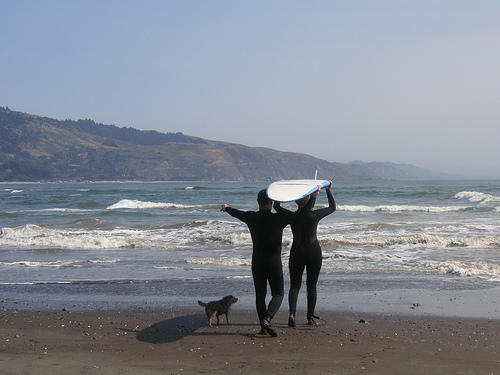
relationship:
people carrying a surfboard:
[219, 186, 323, 337] [264, 176, 332, 205]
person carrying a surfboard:
[274, 184, 337, 326] [240, 163, 392, 219]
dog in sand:
[193, 292, 241, 327] [161, 315, 365, 373]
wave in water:
[412, 252, 498, 287] [5, 175, 499, 287]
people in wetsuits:
[219, 186, 323, 337] [225, 197, 317, 320]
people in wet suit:
[219, 186, 323, 337] [225, 205, 287, 339]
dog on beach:
[193, 292, 241, 327] [1, 276, 498, 372]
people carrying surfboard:
[219, 186, 323, 337] [262, 177, 329, 204]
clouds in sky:
[180, 59, 390, 142] [56, 3, 445, 168]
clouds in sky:
[457, 56, 497, 172] [40, 14, 415, 162]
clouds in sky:
[250, 14, 447, 159] [161, 21, 450, 151]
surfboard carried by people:
[261, 164, 349, 215] [195, 189, 361, 339]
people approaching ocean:
[184, 195, 376, 328] [0, 179, 498, 289]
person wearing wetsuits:
[274, 184, 337, 326] [232, 203, 332, 279]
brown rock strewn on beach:
[346, 305, 392, 335] [26, 134, 176, 360]